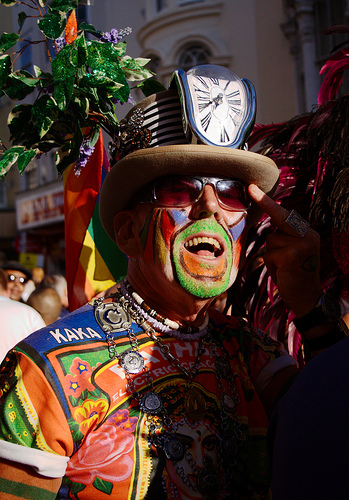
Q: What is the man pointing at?
A: His sunglasses.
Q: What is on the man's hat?
A: A clock.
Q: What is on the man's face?
A: Paint.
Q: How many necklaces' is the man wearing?
A: Four.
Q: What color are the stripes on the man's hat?
A: Black and white.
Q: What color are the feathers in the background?
A: Purple and black.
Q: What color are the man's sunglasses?
A: Purple.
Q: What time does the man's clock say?
A: 7:40.